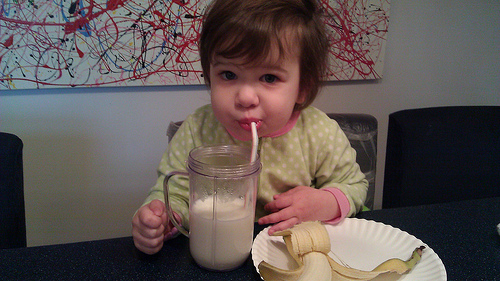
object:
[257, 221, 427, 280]
banana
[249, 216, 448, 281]
plate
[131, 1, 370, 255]
girl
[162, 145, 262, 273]
glass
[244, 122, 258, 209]
straw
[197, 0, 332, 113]
hair